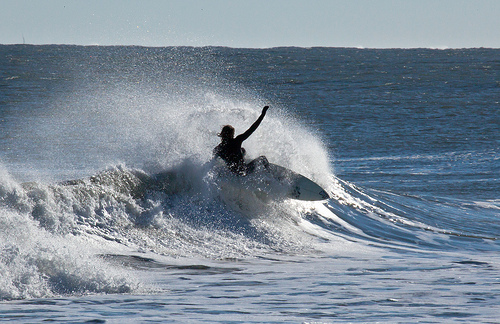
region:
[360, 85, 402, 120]
clear body of water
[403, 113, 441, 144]
clear body of water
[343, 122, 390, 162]
clear body of water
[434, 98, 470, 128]
clear body of water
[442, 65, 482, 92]
clear body of water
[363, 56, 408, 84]
clear body of water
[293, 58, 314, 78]
clear body of water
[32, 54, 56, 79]
clear body of water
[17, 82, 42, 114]
clear body of water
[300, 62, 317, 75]
clear body of water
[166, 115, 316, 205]
person is riding a wave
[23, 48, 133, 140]
a spray of water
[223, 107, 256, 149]
an arm is up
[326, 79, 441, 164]
the ocean is present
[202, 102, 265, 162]
person is getting wet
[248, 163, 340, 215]
surfboard in the water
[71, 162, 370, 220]
a wave is rising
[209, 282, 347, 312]
suds are in the water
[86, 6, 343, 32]
grey sky in background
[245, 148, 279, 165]
a person's knee is shown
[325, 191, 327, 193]
part of a board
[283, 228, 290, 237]
edge of a sea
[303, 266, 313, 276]
side of a sea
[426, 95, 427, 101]
part of a cloud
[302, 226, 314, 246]
edge of a wave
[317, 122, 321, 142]
side of a board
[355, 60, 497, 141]
small ripples on surface of water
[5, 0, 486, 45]
clear sky above water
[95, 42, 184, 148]
mist of water in air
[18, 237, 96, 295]
white sea foam on wave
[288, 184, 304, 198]
black design on white surfboard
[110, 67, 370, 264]
surfer riding white surfboard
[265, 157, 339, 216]
white surfboard in water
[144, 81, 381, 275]
surfer surrounded by water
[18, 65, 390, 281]
surfer riding a wave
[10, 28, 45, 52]
boat on water in distance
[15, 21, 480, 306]
A person is out in the ocean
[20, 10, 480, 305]
A person is on an ocean wave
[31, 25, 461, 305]
A person is out in the sunshine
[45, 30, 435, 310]
A person is close to the beach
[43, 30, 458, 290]
A person is on a surfboard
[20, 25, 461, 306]
A person is getting some exercise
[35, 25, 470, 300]
A person is on their vacation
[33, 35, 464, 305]
A person is getting very wet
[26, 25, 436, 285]
A person is holding their arm up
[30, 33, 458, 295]
A person is enjoying their day